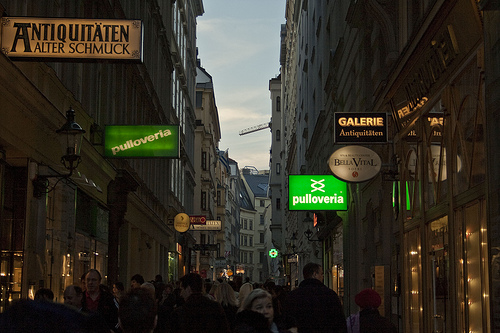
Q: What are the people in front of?
A: Buildings.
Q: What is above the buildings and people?
A: Sky.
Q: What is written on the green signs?
A: Pulloveria.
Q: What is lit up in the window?
A: String lights.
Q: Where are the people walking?
A: Streets.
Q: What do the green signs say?
A: Pulloveria.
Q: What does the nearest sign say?
A: Antiquitaten Alter Schmuck.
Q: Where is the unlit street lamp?
A: To the left.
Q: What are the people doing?
A: Walking.